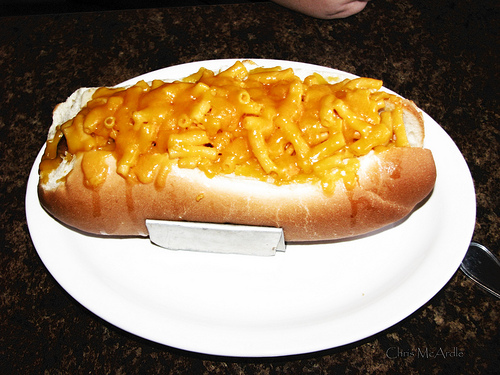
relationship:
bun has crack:
[40, 85, 437, 243] [300, 200, 313, 237]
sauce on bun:
[124, 180, 138, 214] [40, 85, 437, 243]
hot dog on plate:
[41, 63, 434, 243] [24, 57, 479, 362]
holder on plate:
[145, 220, 286, 258] [24, 57, 479, 362]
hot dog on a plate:
[51, 54, 470, 267] [24, 57, 479, 362]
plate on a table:
[14, 218, 487, 370] [4, 7, 499, 374]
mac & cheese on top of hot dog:
[67, 63, 406, 178] [78, 82, 409, 172]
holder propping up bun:
[147, 219, 285, 257] [40, 147, 434, 243]